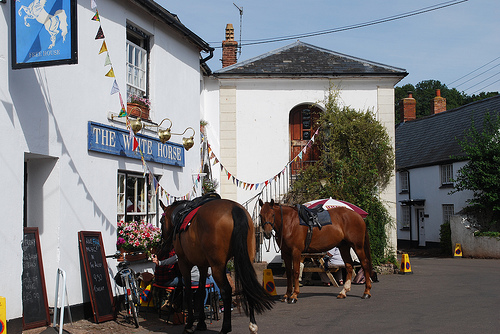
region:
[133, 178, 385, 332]
two horses near building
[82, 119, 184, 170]
plaque on white building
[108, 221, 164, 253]
flowers on window ledge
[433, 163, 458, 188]
window on one of buildings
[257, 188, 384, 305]
horse one looking onward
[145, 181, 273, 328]
horse facing the building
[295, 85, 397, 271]
green plant growing along building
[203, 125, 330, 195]
banner with flags hanging from building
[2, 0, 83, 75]
banner hanging from building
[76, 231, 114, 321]
board outside the building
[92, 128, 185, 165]
white lettering on a blue sign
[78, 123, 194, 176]
blue sign on the white building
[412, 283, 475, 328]
black asphalt of the ground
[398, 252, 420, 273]
yellow cone next to the building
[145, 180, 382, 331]
two horses standing next to the building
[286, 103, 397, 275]
tree growing next to the building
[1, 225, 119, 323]
two chalk boards leaning against the building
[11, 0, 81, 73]
blue and white sign attached to the building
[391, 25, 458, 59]
clear blue skies over the scene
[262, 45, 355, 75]
black shingles of the roof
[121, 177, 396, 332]
two horses are in front of the building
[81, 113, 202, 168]
a sign for the building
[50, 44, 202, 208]
the building is white in color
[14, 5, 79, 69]
the sign has a horse on it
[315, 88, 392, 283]
a tree is behind the horse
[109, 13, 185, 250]
a few windows to the building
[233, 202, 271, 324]
the horse has a black tail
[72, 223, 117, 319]
a chalkboard sign is outside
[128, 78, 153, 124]
some flowers in the window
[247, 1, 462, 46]
power lines are above the building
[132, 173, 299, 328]
horse has brown coat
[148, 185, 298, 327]
horse has black tail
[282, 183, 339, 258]
horse has black saddle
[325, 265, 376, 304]
horse has white feet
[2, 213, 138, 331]
two chalk board leaning on building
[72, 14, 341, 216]
flag banners draped across buildings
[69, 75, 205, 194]
building has blue sign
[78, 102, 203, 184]
blue sign says the white horse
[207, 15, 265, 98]
building has brick fireplace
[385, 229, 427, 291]
yellow cone on street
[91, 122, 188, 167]
a sign on a building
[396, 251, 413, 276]
a yellow cone on the pavement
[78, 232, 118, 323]
a black chalk board sign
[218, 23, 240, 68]
a tall brick chimmeny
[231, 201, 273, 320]
a black horse tail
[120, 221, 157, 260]
a window box with pink and white flowers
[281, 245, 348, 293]
a wooden picnic table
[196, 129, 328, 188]
a multicolored banner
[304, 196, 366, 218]
a red and white umbrella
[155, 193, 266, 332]
a brown and black horse